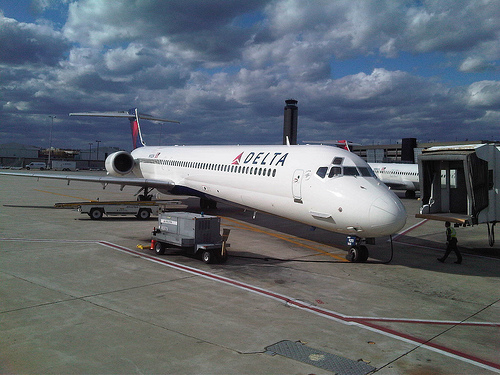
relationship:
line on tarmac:
[92, 236, 484, 372] [2, 240, 272, 335]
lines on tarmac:
[342, 313, 500, 327] [2, 240, 272, 335]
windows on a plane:
[216, 165, 276, 178] [73, 75, 450, 292]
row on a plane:
[139, 155, 278, 176] [73, 75, 450, 292]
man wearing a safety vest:
[435, 220, 463, 265] [443, 225, 458, 240]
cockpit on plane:
[315, 162, 372, 181] [2, 107, 407, 262]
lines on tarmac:
[233, 282, 353, 325] [4, 170, 491, 373]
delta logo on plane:
[230, 150, 288, 167] [2, 107, 407, 262]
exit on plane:
[286, 163, 307, 208] [2, 107, 407, 262]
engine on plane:
[104, 150, 134, 177] [2, 107, 407, 262]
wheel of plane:
[344, 233, 373, 268] [2, 107, 407, 262]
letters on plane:
[241, 152, 293, 167] [2, 107, 407, 262]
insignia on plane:
[233, 147, 245, 164] [2, 107, 407, 262]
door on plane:
[288, 163, 306, 200] [2, 107, 407, 262]